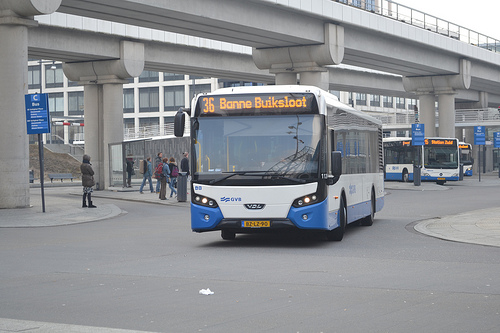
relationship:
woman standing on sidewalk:
[80, 154, 95, 208] [0, 193, 130, 231]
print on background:
[204, 98, 308, 110] [199, 93, 319, 110]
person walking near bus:
[139, 155, 154, 194] [172, 85, 389, 241]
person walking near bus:
[179, 151, 189, 174] [172, 85, 389, 241]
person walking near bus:
[156, 156, 170, 201] [172, 85, 389, 241]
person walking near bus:
[121, 151, 136, 190] [172, 85, 389, 241]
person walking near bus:
[153, 146, 166, 192] [172, 85, 389, 241]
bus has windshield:
[172, 85, 389, 241] [193, 114, 325, 178]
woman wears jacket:
[83, 162, 93, 176] [74, 162, 94, 175]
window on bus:
[343, 123, 360, 160] [172, 85, 389, 241]